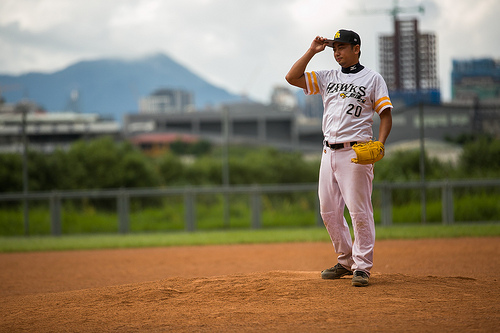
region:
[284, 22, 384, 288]
a baseball player on the court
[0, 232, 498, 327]
the court is red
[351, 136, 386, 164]
his mitt is yellow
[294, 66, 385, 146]
his shirt is white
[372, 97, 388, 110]
yellow stripes on the shirt sleeve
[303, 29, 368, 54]
he is touching his cap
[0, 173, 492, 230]
a fence behind the court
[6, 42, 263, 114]
a hill behind the court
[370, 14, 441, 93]
a building behind the court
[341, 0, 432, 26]
a crane behind the building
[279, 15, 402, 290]
a baseball player on a fieldd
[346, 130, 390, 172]
a yellow glove of baseball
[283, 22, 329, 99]
an arm is bend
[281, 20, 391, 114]
baseball player wears a black cap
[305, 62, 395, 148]
a white shirt with orange stripes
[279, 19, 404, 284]
the player is number 20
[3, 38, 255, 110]
mountains on the background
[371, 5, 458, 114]
a building with many floors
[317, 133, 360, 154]
black belt on white pants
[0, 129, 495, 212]
green trees on a field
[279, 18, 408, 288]
a baseball player in uniform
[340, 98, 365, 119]
a player's number on a baseball uniform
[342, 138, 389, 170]
a light brown leather baseball glove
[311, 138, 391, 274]
the white pants of a baseball uniform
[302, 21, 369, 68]
a person wearing a baseball cap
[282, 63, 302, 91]
the elbow of a person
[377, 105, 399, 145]
the left arm of a person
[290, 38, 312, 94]
the right arm of a person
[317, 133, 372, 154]
a person wearing a black belt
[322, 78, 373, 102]
a team name on the front of a baseball uniform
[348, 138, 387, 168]
A baseball glove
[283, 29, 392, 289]
A male baseball player for the Hawks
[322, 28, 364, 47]
A black cap belonging to a man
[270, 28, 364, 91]
A man touching his cap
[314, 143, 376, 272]
A baseball players white pants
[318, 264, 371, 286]
A man's black shoes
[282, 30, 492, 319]
A baseball player standing in dirt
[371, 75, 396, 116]
Yellow stripes on a white sleeve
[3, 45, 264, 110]
A mountain in the background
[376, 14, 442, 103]
A high rise building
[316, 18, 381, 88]
the head of a man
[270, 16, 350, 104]
the arm of a man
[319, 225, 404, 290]
the feet of a man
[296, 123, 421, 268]
the legs of a man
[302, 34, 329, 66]
the hand of a man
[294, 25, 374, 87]
a man wearing a cap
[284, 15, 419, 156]
a man wearing a shirt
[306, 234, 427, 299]
a man wearing shoes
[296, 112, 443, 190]
a man wearing a baseball glove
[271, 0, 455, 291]
a man standing on dirt